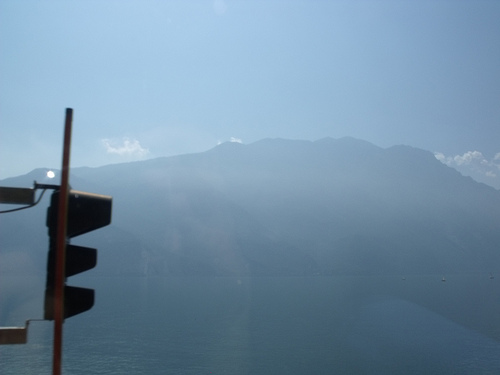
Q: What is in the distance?
A: Mountain.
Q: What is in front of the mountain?
A: Water.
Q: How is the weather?
A: Partly cloudy.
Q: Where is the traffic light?
A: On the left of the picture.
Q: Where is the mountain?
A: On the other side of the water.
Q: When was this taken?
A: During day hours.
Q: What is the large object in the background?
A: Mountain.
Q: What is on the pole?
A: Red light.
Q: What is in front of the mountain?
A: Water.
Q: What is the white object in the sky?
A: Clouds.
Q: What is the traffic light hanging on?
A: Pole.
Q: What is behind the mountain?
A: Clouds.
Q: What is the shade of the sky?
A: Blue.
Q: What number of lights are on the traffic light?
A: 3.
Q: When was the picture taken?
A: Daytime.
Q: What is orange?
A: Pole.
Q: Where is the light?
A: To the left.